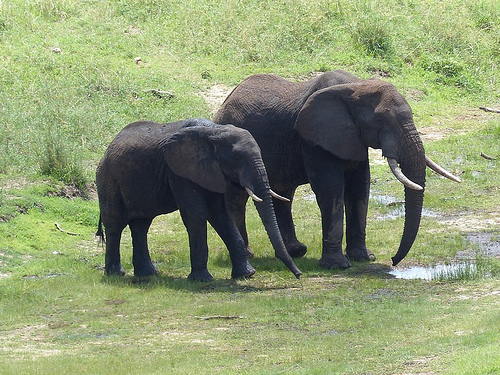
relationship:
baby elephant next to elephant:
[93, 120, 304, 283] [216, 66, 462, 272]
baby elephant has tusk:
[93, 120, 304, 283] [243, 187, 264, 204]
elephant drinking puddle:
[216, 66, 462, 272] [373, 261, 477, 283]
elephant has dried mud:
[216, 66, 462, 272] [322, 193, 352, 268]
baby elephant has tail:
[93, 120, 304, 283] [96, 209, 106, 240]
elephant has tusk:
[216, 66, 462, 272] [389, 157, 424, 193]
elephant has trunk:
[216, 66, 462, 272] [390, 117, 427, 266]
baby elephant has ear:
[93, 120, 304, 283] [161, 124, 228, 195]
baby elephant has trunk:
[93, 120, 304, 283] [248, 156, 303, 280]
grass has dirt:
[1, 3, 499, 374] [2, 318, 258, 363]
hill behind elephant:
[3, 2, 500, 252] [216, 66, 462, 272]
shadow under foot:
[214, 251, 397, 282] [321, 255, 353, 270]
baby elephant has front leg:
[93, 120, 304, 283] [207, 197, 256, 282]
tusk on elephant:
[425, 156, 461, 186] [216, 66, 462, 272]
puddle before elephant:
[373, 261, 477, 283] [216, 66, 462, 272]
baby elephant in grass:
[93, 120, 304, 283] [1, 3, 499, 374]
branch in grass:
[54, 220, 83, 238] [1, 3, 499, 374]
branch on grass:
[54, 220, 83, 238] [1, 3, 499, 374]